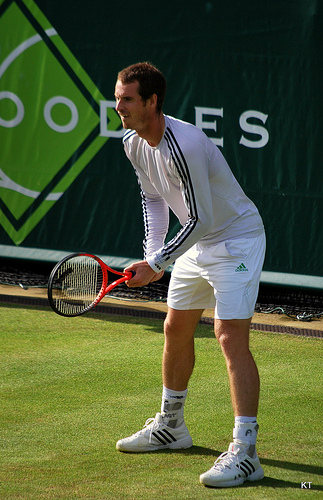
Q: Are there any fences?
A: No, there are no fences.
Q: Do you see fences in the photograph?
A: No, there are no fences.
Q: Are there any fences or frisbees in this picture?
A: No, there are no fences or frisbees.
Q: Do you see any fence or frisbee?
A: No, there are no fences or frisbees.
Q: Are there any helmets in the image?
A: No, there are no helmets.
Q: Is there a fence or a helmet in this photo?
A: No, there are no helmets or fences.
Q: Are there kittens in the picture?
A: No, there are no kittens.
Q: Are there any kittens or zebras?
A: No, there are no kittens or zebras.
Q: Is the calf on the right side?
A: Yes, the calf is on the right of the image.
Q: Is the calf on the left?
A: No, the calf is on the right of the image.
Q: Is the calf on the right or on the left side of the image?
A: The calf is on the right of the image.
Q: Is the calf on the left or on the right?
A: The calf is on the right of the image.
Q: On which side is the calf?
A: The calf is on the right of the image.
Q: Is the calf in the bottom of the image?
A: Yes, the calf is in the bottom of the image.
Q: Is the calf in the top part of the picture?
A: No, the calf is in the bottom of the image.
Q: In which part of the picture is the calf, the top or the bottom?
A: The calf is in the bottom of the image.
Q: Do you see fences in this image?
A: No, there are no fences.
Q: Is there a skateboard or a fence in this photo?
A: No, there are no fences or skateboards.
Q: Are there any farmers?
A: No, there are no farmers.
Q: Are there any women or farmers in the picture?
A: No, there are no farmers or women.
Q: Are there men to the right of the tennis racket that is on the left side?
A: Yes, there is a man to the right of the tennis racket.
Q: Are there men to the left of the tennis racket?
A: No, the man is to the right of the tennis racket.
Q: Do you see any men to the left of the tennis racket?
A: No, the man is to the right of the tennis racket.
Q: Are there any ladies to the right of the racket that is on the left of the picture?
A: No, there is a man to the right of the tennis racket.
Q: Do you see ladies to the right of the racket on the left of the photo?
A: No, there is a man to the right of the tennis racket.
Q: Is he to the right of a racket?
A: Yes, the man is to the right of a racket.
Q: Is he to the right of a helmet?
A: No, the man is to the right of a racket.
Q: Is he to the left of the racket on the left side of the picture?
A: No, the man is to the right of the racket.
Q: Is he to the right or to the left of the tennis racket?
A: The man is to the right of the tennis racket.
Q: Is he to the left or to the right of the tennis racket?
A: The man is to the right of the tennis racket.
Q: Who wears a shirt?
A: The man wears a shirt.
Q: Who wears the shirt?
A: The man wears a shirt.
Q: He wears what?
A: The man wears a shirt.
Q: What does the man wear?
A: The man wears a shirt.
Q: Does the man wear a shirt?
A: Yes, the man wears a shirt.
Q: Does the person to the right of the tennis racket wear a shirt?
A: Yes, the man wears a shirt.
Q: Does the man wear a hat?
A: No, the man wears a shirt.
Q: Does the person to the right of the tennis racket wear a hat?
A: No, the man wears a shirt.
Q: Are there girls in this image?
A: No, there are no girls.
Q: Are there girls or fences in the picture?
A: No, there are no girls or fences.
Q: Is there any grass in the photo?
A: Yes, there is grass.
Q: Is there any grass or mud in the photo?
A: Yes, there is grass.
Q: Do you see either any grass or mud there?
A: Yes, there is grass.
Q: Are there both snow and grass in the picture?
A: No, there is grass but no snow.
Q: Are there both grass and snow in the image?
A: No, there is grass but no snow.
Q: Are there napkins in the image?
A: No, there are no napkins.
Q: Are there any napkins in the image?
A: No, there are no napkins.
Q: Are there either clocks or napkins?
A: No, there are no napkins or clocks.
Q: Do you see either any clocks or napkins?
A: No, there are no napkins or clocks.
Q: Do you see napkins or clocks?
A: No, there are no napkins or clocks.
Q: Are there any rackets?
A: Yes, there is a racket.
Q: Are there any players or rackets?
A: Yes, there is a racket.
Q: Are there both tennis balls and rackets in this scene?
A: No, there is a racket but no tennis balls.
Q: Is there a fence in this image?
A: No, there are no fences.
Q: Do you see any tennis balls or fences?
A: No, there are no fences or tennis balls.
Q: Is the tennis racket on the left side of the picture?
A: Yes, the tennis racket is on the left of the image.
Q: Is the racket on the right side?
A: No, the racket is on the left of the image.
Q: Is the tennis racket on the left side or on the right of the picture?
A: The tennis racket is on the left of the image.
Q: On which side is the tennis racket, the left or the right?
A: The tennis racket is on the left of the image.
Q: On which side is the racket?
A: The racket is on the left of the image.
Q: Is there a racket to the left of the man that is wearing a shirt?
A: Yes, there is a racket to the left of the man.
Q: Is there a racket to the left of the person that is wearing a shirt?
A: Yes, there is a racket to the left of the man.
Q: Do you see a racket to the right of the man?
A: No, the racket is to the left of the man.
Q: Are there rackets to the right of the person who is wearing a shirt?
A: No, the racket is to the left of the man.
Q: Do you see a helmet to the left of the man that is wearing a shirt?
A: No, there is a racket to the left of the man.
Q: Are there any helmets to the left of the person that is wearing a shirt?
A: No, there is a racket to the left of the man.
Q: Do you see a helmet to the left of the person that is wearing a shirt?
A: No, there is a racket to the left of the man.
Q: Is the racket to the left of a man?
A: Yes, the racket is to the left of a man.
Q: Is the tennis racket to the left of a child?
A: No, the tennis racket is to the left of a man.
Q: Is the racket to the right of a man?
A: No, the racket is to the left of a man.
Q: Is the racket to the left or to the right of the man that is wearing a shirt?
A: The racket is to the left of the man.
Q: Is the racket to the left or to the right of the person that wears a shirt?
A: The racket is to the left of the man.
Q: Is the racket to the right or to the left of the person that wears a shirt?
A: The racket is to the left of the man.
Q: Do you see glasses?
A: No, there are no glasses.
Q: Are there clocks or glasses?
A: No, there are no glasses or clocks.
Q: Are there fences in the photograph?
A: No, there are no fences.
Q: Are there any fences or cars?
A: No, there are no fences or cars.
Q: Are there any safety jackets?
A: No, there are no safety jackets.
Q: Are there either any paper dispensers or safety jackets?
A: No, there are no safety jackets or paper dispensers.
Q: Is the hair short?
A: Yes, the hair is short.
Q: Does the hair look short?
A: Yes, the hair is short.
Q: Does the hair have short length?
A: Yes, the hair is short.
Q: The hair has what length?
A: The hair is short.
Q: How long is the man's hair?
A: The hair is short.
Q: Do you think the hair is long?
A: No, the hair is short.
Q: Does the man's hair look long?
A: No, the hair is short.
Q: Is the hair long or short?
A: The hair is short.